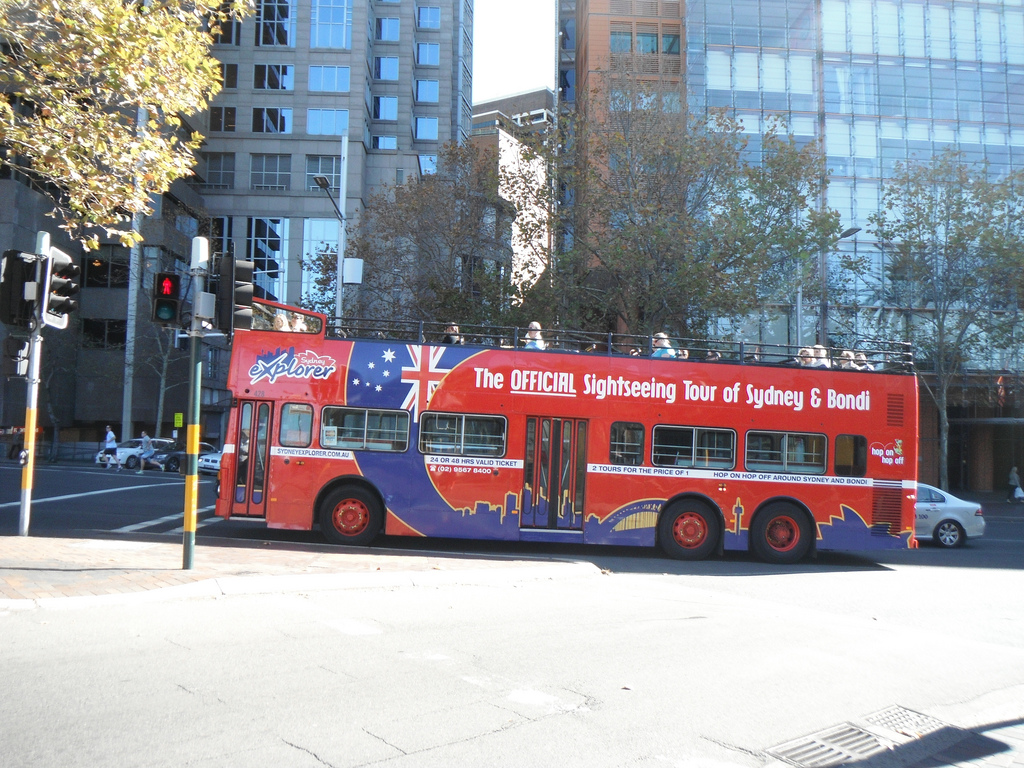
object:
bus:
[214, 330, 918, 564]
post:
[180, 338, 204, 570]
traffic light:
[156, 274, 180, 321]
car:
[915, 482, 986, 551]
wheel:
[751, 500, 816, 564]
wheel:
[659, 497, 720, 560]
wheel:
[318, 484, 386, 545]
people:
[102, 425, 167, 476]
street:
[0, 445, 216, 547]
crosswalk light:
[151, 272, 179, 323]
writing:
[473, 366, 873, 413]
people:
[441, 319, 877, 373]